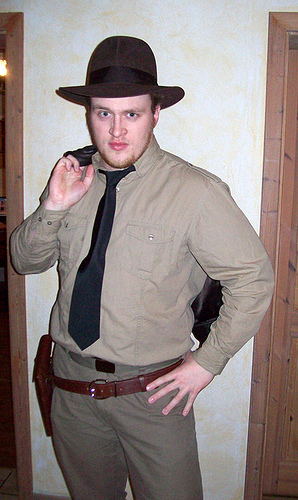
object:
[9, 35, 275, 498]
man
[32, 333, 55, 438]
holster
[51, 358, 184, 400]
belt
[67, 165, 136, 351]
tie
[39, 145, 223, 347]
jacket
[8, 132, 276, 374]
shirt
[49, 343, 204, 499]
pants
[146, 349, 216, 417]
hand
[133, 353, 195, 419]
hip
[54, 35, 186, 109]
cowboy hat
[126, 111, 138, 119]
eye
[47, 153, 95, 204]
hand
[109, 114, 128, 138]
nose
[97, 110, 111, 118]
eye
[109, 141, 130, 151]
lips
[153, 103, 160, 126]
ear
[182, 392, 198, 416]
pinkie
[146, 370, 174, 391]
pointer finger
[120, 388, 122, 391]
hole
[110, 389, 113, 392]
hole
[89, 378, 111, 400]
buckle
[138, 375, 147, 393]
loop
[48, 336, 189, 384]
waist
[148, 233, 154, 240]
button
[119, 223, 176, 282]
pocket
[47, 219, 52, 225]
button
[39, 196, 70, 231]
cuff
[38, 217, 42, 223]
button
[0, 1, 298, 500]
wall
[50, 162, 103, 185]
shoulder